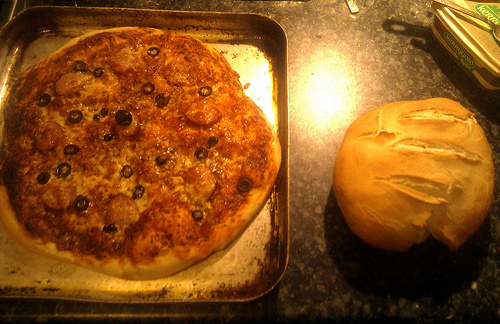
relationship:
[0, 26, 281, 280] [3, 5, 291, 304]
pizza on pan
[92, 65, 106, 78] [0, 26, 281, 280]
olive on pizza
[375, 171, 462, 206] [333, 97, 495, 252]
cut in bread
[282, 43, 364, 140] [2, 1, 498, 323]
light on counter top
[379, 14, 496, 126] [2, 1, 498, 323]
shadow on counter top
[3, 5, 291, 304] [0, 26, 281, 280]
crust of pizza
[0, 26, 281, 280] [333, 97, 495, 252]
pizza next to bread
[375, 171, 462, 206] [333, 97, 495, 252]
cut on bread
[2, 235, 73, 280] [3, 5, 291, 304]
shadow on pan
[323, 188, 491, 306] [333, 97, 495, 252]
shadow by bread